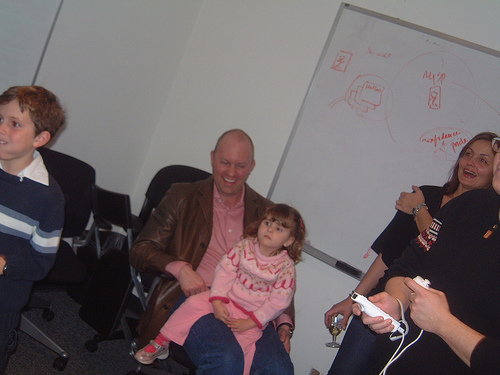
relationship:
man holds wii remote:
[351, 127, 496, 374] [342, 276, 436, 374]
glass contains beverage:
[325, 316, 342, 348] [329, 326, 341, 335]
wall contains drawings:
[218, 1, 497, 281] [333, 22, 452, 150]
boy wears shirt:
[2, 81, 70, 358] [5, 157, 71, 308]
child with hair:
[133, 200, 303, 373] [255, 195, 302, 255]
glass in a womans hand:
[323, 312, 344, 348] [321, 298, 352, 332]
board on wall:
[259, 6, 499, 290] [129, 3, 499, 374]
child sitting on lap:
[133, 203, 307, 375] [184, 282, 293, 371]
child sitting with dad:
[133, 203, 307, 375] [124, 127, 296, 373]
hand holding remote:
[348, 291, 402, 334] [350, 292, 401, 334]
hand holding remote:
[400, 273, 450, 332] [350, 292, 401, 334]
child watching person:
[133, 203, 307, 375] [345, 132, 484, 372]